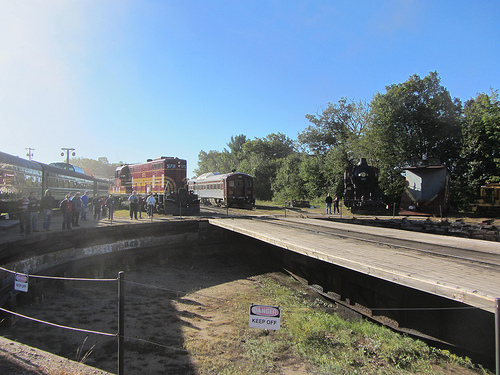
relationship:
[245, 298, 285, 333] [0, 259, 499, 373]
sign on fence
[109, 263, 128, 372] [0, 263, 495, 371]
fence post holding wire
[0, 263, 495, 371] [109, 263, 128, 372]
wire attached to fence post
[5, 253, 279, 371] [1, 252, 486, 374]
shade on ground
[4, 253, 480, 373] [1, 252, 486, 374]
grass on ground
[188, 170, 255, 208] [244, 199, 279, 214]
train on tracks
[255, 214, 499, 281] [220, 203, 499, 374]
train tracks are on bridge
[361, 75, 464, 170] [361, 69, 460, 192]
leaves are on tree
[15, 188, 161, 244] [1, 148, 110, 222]
people are standing near train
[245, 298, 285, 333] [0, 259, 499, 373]
danger sign on fence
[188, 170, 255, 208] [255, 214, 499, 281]
train driving on train tracks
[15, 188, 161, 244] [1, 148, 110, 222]
people are to side of train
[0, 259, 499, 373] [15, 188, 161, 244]
fence keeping away people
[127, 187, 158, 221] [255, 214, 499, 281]
two people standing to right of train tracks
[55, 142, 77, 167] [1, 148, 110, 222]
telephone pole by train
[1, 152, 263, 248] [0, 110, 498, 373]
several trains are at station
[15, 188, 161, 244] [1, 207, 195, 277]
people are on platform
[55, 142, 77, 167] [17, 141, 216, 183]
telephone pole in distance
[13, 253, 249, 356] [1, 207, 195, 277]
dirt below platform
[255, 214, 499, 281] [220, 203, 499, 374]
train tracks extend across bridge